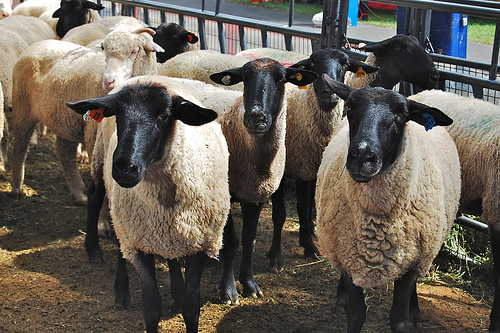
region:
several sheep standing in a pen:
[0, 0, 468, 305]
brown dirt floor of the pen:
[10, 242, 75, 314]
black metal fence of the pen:
[211, 8, 311, 57]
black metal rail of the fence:
[182, 5, 294, 40]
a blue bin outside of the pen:
[388, 0, 476, 61]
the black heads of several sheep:
[89, 45, 425, 188]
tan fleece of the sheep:
[384, 158, 444, 260]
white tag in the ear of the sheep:
[211, 63, 240, 91]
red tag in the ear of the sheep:
[82, 98, 112, 123]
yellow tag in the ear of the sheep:
[356, 60, 370, 80]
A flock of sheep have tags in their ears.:
[78, 10, 495, 225]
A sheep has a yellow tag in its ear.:
[232, 68, 340, 113]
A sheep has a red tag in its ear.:
[86, 98, 117, 155]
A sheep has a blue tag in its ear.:
[396, 85, 459, 146]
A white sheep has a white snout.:
[18, 28, 188, 94]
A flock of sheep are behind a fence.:
[15, 3, 490, 223]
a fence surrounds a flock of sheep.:
[166, 3, 488, 98]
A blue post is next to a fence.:
[395, 5, 477, 66]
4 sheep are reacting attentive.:
[76, 47, 426, 209]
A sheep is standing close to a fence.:
[374, 24, 448, 99]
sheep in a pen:
[62, 70, 243, 331]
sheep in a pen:
[302, 68, 474, 331]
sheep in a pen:
[1, 24, 162, 209]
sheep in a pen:
[222, 41, 374, 273]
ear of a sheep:
[165, 90, 220, 138]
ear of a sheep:
[62, 87, 117, 126]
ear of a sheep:
[317, 68, 366, 103]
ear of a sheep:
[402, 92, 455, 134]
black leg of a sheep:
[125, 245, 170, 332]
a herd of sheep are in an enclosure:
[5, 3, 483, 326]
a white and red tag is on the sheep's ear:
[70, 97, 109, 126]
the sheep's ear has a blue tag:
[409, 101, 455, 133]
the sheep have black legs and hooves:
[78, 176, 494, 331]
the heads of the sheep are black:
[81, 43, 440, 186]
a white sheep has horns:
[82, 17, 161, 89]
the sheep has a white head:
[94, 2, 164, 95]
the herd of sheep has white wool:
[8, 6, 498, 282]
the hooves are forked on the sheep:
[218, 278, 266, 310]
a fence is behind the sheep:
[78, 4, 498, 118]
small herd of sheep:
[0, 50, 496, 324]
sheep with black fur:
[80, 90, 195, 184]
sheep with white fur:
[94, 53, 141, 83]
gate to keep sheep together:
[116, 0, 321, 49]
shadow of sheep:
[8, 204, 84, 326]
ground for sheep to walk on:
[1, 243, 123, 330]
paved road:
[345, 25, 382, 37]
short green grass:
[470, 18, 487, 41]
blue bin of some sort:
[396, 4, 466, 54]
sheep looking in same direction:
[68, 61, 413, 279]